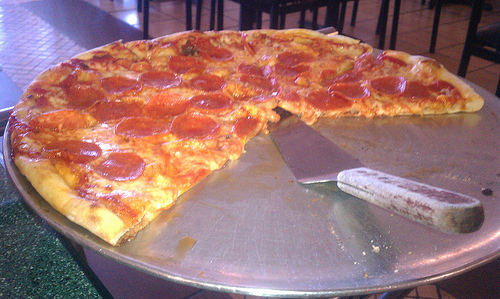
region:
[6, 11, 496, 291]
pizza is on a silver tray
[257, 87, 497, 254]
the spatula has a wood handle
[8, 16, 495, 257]
pizza has lots of pepperonis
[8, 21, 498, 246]
pizza is covered in cheese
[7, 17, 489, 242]
the cheese on the pizza is melted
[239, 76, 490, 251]
the spatula is silver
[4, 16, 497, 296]
the pizza tray is silver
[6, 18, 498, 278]
the pizza is on a serving tray with a spatula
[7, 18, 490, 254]
pepperoni is red in color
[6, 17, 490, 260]
cheese is yellow and orange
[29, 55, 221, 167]
the pizza has redtoppings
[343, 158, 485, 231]
the handle is made of wood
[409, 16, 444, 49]
the floor is tiled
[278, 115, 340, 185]
the blade is mettalic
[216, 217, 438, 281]
the surface is silver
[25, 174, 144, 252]
the crust is brown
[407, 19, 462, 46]
the tiles are brown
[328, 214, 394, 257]
the shadow is on the surface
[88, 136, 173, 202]
the pizza is made of cheese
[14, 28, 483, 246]
the pizza looks tasty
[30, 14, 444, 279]
This is a pizza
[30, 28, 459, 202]
The pizza has pepperoni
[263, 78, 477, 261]
A spatula serves the pizza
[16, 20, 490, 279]
The pizza is on a tray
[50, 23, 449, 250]
The pizza tray is metal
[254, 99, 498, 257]
The spatula is metal and wood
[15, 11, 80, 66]
The floor has tiles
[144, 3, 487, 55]
The chairs are black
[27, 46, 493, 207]
Half of the pizza is gone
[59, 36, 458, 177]
The pizza has cheese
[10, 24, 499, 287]
pizza is nearly half gone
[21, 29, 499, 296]
large pepperoni and cheese pizza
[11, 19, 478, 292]
pizza on large aluminum tray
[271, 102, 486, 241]
spatula with wood handle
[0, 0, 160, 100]
patterned brick walkway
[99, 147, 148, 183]
shiny greasy pepperoni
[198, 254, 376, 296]
pan is reflecting light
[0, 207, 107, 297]
green or dark blue carpet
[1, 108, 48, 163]
cheese spilt over edge of crust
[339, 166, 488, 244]
wood handle has lots of wear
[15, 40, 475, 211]
Pepperoni pizza cut.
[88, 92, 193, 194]
Cheese and pepperoni pizza.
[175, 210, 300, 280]
Silver tray with a pizza on it.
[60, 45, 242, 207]
Hot pizza at a restaurant.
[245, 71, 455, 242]
Spatula on the tray.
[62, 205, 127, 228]
Pizza crust.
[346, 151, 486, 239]
Wooden handled spatula.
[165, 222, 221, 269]
Pizza grease on the tray.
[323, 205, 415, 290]
Crumbs on the silver tray.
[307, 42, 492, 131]
A slice of pizza.